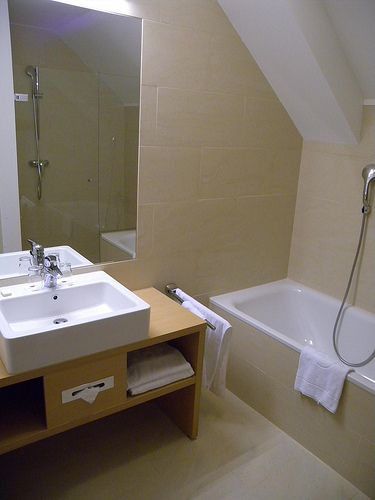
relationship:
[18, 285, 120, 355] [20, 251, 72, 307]
glass next to faucet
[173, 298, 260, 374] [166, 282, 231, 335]
towel on rack